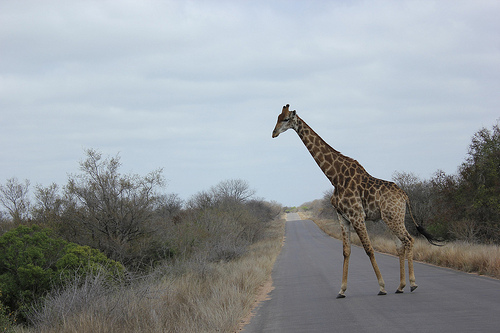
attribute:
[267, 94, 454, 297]
giraffe — brown, white, standing, beige, tall, walking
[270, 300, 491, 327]
ground — paved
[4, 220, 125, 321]
bush — green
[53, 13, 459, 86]
sky — cloudy, overcast, grey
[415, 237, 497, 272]
grass — yellow, dry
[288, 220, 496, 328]
road — paved, straight, long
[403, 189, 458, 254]
tail — black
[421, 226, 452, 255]
hair — black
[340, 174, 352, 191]
spot — brown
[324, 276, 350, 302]
hoof — black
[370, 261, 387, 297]
hoof — black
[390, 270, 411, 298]
hoof — black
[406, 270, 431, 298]
hoof — black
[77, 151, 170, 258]
tree — leafless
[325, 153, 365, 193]
spots — brown